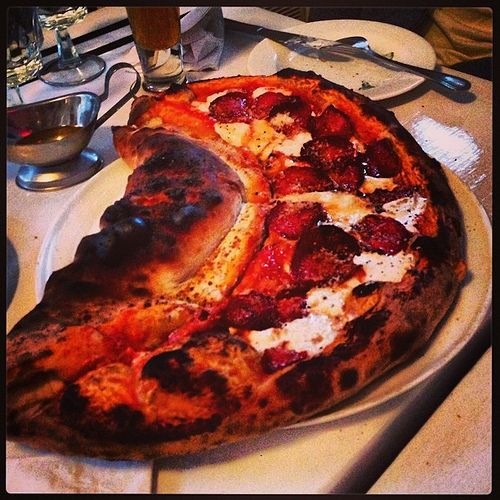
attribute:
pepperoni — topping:
[306, 127, 349, 164]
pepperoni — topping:
[295, 220, 351, 280]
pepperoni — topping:
[349, 209, 409, 254]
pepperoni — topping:
[363, 133, 403, 180]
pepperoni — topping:
[299, 96, 350, 141]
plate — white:
[247, 18, 438, 102]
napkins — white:
[2, 450, 147, 487]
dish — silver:
[8, 76, 208, 217]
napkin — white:
[5, 435, 155, 496]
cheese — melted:
[268, 289, 335, 342]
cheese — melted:
[324, 160, 412, 248]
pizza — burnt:
[7, 66, 466, 463]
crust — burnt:
[388, 115, 466, 361]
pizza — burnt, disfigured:
[105, 70, 475, 407]